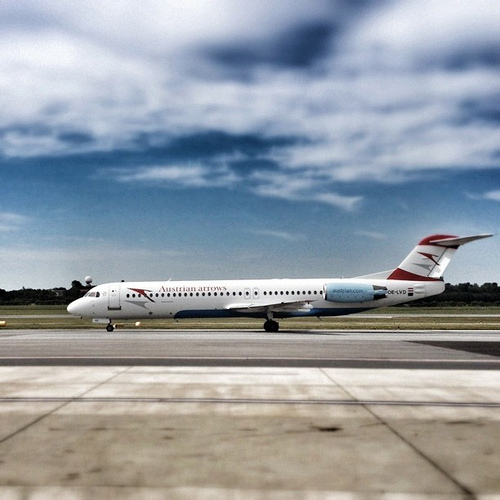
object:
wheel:
[260, 318, 278, 333]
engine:
[320, 279, 397, 303]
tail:
[388, 225, 493, 280]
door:
[106, 285, 124, 310]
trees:
[70, 278, 85, 299]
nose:
[66, 285, 93, 319]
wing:
[225, 293, 318, 311]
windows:
[84, 291, 97, 298]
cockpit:
[63, 283, 134, 322]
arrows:
[414, 247, 442, 268]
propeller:
[320, 281, 347, 305]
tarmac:
[0, 305, 499, 500]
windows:
[187, 286, 194, 298]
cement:
[356, 397, 500, 500]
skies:
[0, 0, 497, 285]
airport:
[0, 304, 499, 499]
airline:
[67, 234, 492, 334]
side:
[67, 228, 499, 334]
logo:
[363, 284, 406, 298]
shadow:
[177, 312, 348, 334]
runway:
[0, 315, 493, 398]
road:
[0, 322, 499, 384]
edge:
[345, 322, 484, 335]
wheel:
[103, 320, 118, 332]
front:
[61, 278, 151, 335]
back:
[172, 276, 323, 288]